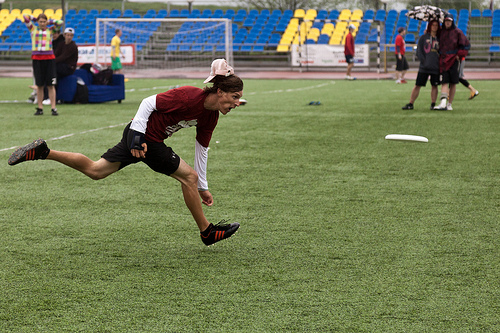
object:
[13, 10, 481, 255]
people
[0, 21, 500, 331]
field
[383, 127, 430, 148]
frisbee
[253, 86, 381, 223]
air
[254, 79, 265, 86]
chairs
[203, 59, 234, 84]
cap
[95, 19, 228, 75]
net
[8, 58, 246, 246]
man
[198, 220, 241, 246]
shoes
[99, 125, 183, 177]
shorts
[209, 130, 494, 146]
lines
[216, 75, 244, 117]
head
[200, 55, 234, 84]
hat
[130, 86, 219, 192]
shirt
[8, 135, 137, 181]
leg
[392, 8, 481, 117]
people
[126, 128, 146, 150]
glove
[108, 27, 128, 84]
man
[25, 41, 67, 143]
woman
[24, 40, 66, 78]
sweater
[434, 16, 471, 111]
man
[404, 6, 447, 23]
umbrella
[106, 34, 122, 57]
shirt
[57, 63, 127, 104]
sofa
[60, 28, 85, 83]
man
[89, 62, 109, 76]
hat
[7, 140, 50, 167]
stripes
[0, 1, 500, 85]
background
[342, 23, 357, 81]
man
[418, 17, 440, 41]
hood